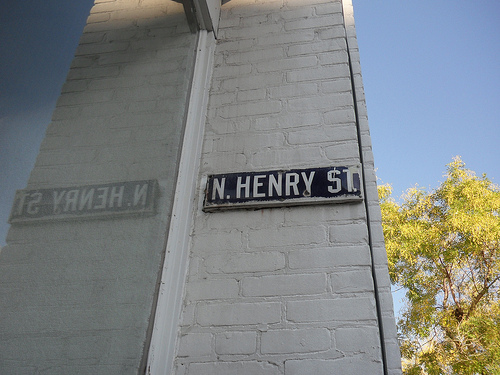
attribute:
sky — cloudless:
[354, 1, 499, 216]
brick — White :
[245, 224, 332, 252]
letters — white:
[265, 171, 283, 198]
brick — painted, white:
[230, 279, 307, 354]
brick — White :
[282, 89, 336, 119]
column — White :
[168, 1, 402, 372]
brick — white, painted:
[223, 1, 380, 360]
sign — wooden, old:
[209, 157, 360, 207]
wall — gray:
[232, 42, 347, 148]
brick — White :
[242, 73, 342, 130]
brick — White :
[258, 26, 318, 48]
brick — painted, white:
[239, 269, 327, 301]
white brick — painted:
[258, 327, 335, 354]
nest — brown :
[451, 305, 465, 324]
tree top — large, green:
[383, 162, 494, 374]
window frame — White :
[146, 29, 216, 374]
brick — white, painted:
[241, 270, 331, 300]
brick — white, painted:
[196, 297, 288, 327]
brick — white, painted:
[201, 248, 290, 275]